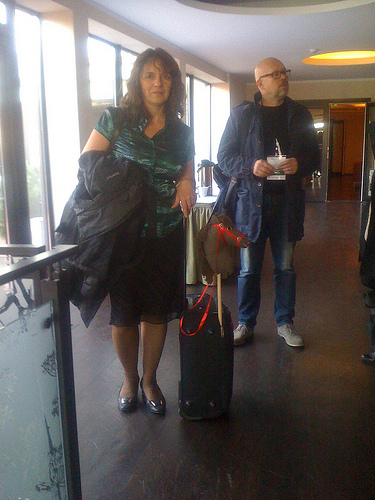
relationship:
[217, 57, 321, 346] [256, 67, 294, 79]
man wearing glasses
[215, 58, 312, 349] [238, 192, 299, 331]
man wearing jeans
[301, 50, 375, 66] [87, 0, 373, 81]
ceiling light in ceiling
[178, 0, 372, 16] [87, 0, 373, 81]
hole in ceiling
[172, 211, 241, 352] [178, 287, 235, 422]
pony in suitcase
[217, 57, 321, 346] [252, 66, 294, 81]
man with glasses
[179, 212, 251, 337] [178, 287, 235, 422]
pony sticking out of suitcase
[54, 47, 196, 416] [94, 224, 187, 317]
lady wearing skirt